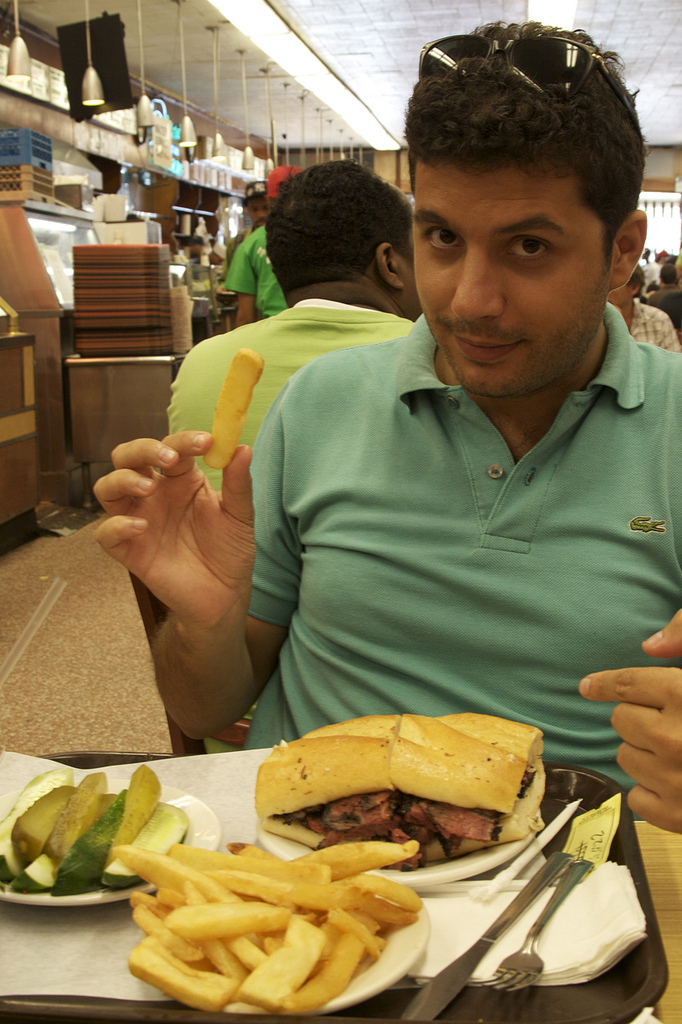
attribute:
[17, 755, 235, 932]
plate — white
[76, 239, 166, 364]
trays — stack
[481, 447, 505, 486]
button — one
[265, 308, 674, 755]
shirt — man's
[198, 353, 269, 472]
french fry — yellow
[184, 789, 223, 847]
plate — white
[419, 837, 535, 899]
plate — white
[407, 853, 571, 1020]
knife — metal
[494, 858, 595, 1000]
fork — metal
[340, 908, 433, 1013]
plate — white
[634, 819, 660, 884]
table — wooden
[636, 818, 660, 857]
table — wooden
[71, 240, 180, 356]
trays — plastic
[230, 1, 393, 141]
ceiling — white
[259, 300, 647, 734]
shirt — green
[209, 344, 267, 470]
french fry — golden brown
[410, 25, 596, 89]
glasses — black